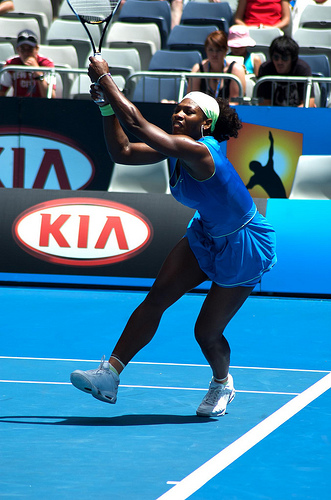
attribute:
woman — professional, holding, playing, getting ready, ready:
[70, 56, 277, 421]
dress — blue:
[167, 140, 277, 286]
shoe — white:
[71, 356, 121, 404]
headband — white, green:
[178, 90, 220, 134]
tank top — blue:
[166, 138, 257, 238]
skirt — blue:
[184, 210, 278, 287]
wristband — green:
[97, 102, 115, 116]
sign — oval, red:
[10, 195, 155, 267]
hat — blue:
[16, 30, 37, 44]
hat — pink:
[227, 25, 257, 48]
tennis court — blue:
[4, 97, 327, 498]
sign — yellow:
[227, 129, 303, 197]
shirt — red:
[3, 59, 55, 98]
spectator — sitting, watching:
[2, 31, 57, 99]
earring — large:
[201, 124, 209, 141]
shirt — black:
[255, 60, 316, 107]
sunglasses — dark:
[269, 52, 295, 63]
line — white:
[156, 371, 330, 498]